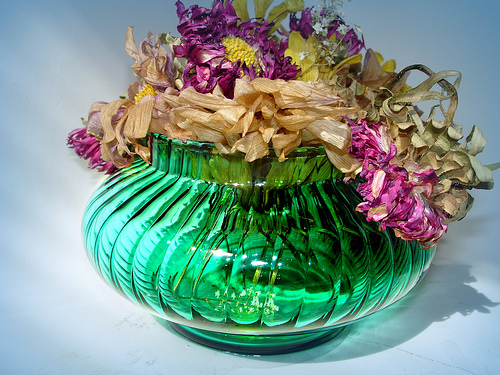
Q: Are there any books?
A: No, there are no books.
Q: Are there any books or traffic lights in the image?
A: No, there are no books or traffic lights.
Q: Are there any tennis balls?
A: No, there are no tennis balls.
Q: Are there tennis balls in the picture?
A: No, there are no tennis balls.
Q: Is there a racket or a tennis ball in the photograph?
A: No, there are no tennis balls or rackets.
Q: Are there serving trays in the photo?
A: No, there are no serving trays.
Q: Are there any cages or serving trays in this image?
A: No, there are no serving trays or cages.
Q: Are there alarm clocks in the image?
A: No, there are no alarm clocks.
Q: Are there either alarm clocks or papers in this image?
A: No, there are no alarm clocks or papers.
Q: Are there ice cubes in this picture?
A: No, there are no ice cubes.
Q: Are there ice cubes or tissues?
A: No, there are no ice cubes or tissues.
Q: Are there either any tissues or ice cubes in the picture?
A: No, there are no ice cubes or tissues.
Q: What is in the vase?
A: The flowers are in the vase.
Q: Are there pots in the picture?
A: Yes, there is a pot.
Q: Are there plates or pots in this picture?
A: Yes, there is a pot.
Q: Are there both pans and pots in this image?
A: No, there is a pot but no pans.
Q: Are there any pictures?
A: No, there are no pictures.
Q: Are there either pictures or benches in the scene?
A: No, there are no pictures or benches.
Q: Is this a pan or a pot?
A: This is a pot.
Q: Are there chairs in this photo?
A: No, there are no chairs.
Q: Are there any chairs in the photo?
A: No, there are no chairs.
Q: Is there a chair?
A: No, there are no chairs.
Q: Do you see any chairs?
A: No, there are no chairs.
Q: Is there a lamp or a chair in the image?
A: No, there are no chairs or lamps.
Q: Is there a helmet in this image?
A: No, there are no helmets.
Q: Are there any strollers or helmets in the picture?
A: No, there are no helmets or strollers.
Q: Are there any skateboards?
A: No, there are no skateboards.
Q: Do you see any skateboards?
A: No, there are no skateboards.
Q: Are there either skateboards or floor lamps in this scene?
A: No, there are no skateboards or floor lamps.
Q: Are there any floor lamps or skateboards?
A: No, there are no skateboards or floor lamps.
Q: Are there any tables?
A: Yes, there is a table.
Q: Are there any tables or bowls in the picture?
A: Yes, there is a table.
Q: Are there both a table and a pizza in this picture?
A: No, there is a table but no pizzas.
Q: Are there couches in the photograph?
A: No, there are no couches.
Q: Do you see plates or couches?
A: No, there are no couches or plates.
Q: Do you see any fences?
A: No, there are no fences.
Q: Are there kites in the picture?
A: No, there are no kites.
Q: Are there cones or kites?
A: No, there are no kites or cones.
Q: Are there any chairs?
A: No, there are no chairs.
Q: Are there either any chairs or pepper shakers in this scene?
A: No, there are no chairs or pepper shakers.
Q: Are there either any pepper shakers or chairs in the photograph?
A: No, there are no chairs or pepper shakers.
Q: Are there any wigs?
A: No, there are no wigs.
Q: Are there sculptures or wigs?
A: No, there are no wigs or sculptures.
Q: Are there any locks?
A: No, there are no locks.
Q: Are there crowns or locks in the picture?
A: No, there are no locks or crowns.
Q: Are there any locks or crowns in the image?
A: No, there are no locks or crowns.